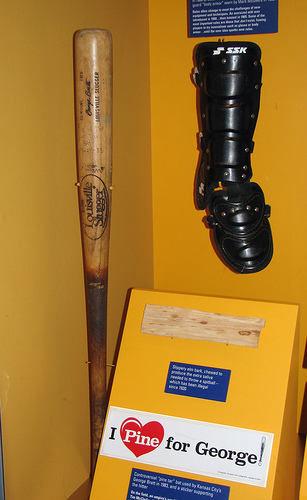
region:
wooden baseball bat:
[57, 22, 128, 470]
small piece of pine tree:
[118, 297, 279, 352]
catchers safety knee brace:
[161, 39, 290, 317]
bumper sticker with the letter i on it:
[66, 397, 288, 481]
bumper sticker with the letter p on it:
[67, 396, 290, 495]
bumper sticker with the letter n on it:
[63, 399, 279, 480]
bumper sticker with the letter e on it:
[87, 393, 295, 486]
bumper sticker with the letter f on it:
[78, 401, 292, 493]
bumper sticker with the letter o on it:
[47, 401, 283, 493]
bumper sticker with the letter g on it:
[74, 404, 284, 475]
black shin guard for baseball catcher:
[189, 31, 285, 274]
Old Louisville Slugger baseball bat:
[59, 21, 116, 400]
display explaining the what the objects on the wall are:
[92, 285, 294, 495]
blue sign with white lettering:
[166, 354, 230, 404]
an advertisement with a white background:
[94, 415, 265, 472]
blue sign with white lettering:
[127, 470, 230, 498]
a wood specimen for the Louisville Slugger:
[145, 300, 269, 349]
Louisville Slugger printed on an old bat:
[75, 164, 120, 242]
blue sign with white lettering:
[182, 1, 286, 43]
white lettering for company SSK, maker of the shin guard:
[211, 44, 253, 58]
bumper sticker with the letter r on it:
[65, 401, 295, 480]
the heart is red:
[118, 414, 167, 460]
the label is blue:
[162, 356, 236, 405]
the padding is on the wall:
[189, 35, 275, 274]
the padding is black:
[187, 37, 279, 273]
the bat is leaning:
[70, 24, 115, 488]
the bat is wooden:
[67, 25, 117, 498]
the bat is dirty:
[71, 26, 116, 497]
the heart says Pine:
[123, 425, 158, 449]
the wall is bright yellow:
[0, 0, 305, 498]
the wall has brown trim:
[64, 474, 95, 498]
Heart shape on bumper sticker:
[118, 414, 166, 462]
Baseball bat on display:
[60, 26, 121, 450]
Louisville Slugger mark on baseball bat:
[61, 169, 122, 261]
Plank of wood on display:
[143, 295, 270, 406]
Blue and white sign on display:
[153, 355, 235, 408]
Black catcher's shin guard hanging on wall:
[181, 40, 286, 279]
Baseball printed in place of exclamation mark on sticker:
[251, 432, 270, 479]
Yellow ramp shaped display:
[84, 280, 305, 498]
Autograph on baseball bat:
[67, 68, 112, 129]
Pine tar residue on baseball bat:
[74, 271, 111, 448]